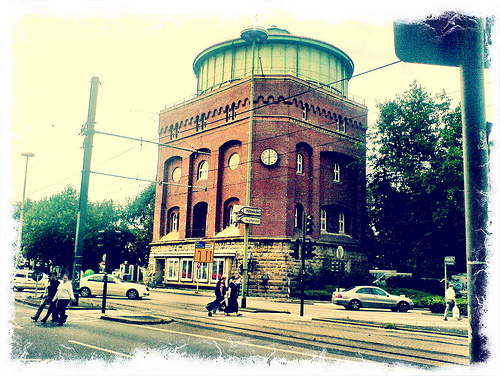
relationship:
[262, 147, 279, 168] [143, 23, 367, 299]
clock on front of building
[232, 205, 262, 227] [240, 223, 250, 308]
street sign on pole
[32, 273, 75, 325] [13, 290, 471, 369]
people crossing street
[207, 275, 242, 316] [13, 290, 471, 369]
people crossing street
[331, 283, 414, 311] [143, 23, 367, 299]
car by building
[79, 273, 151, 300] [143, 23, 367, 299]
car by building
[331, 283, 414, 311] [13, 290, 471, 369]
car on street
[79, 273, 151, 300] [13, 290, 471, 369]
car on street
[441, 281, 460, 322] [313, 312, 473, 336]
man walking on sidewalk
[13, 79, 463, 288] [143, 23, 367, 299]
trees behind building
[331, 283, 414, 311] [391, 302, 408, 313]
car has a front tire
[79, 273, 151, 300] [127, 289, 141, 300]
car has a front tire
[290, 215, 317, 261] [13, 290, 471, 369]
trafic lights by street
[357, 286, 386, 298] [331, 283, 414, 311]
window on car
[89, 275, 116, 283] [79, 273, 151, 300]
window on car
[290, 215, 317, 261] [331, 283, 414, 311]
trafic lights behind car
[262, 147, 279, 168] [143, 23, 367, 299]
clock on building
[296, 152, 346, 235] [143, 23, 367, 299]
windows on building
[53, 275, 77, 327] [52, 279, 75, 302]
woman wearing a sweater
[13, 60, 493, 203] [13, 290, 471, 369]
wires above street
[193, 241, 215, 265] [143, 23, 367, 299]
sign by building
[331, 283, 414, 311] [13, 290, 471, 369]
car driving on street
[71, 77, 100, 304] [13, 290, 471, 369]
telephone pole by street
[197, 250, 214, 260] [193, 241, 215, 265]
arrows on sign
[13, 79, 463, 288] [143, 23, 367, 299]
trees growing behind building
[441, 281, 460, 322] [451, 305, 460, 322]
man holding bag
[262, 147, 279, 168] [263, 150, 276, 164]
clock has a face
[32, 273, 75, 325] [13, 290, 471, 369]
people walking across street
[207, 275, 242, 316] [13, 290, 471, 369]
people walking across street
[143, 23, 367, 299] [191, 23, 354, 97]
building has a top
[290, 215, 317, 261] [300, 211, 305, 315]
trafic lights on a pole